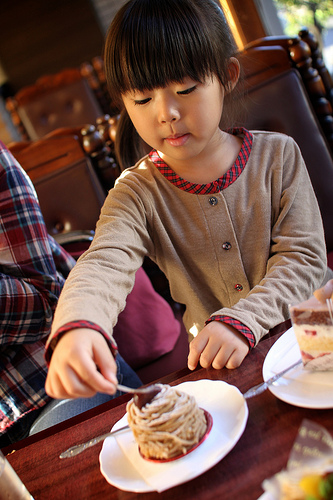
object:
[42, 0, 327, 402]
girl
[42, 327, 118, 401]
hand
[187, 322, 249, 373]
hand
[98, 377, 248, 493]
plate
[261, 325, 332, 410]
plate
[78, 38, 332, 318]
chair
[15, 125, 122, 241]
chair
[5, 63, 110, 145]
chair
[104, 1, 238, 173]
hair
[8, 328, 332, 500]
table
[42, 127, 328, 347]
shirt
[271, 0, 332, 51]
tree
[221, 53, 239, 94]
ear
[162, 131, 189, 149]
lips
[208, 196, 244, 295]
buttons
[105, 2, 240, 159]
head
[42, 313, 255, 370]
cuffs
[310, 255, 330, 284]
elbow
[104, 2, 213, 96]
bangs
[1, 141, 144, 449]
person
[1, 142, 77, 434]
shirt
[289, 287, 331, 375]
dessert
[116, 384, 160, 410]
spoon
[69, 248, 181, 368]
purse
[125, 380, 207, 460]
spaghetti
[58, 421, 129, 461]
utensil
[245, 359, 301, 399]
utensil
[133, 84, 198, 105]
eyes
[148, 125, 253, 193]
collar